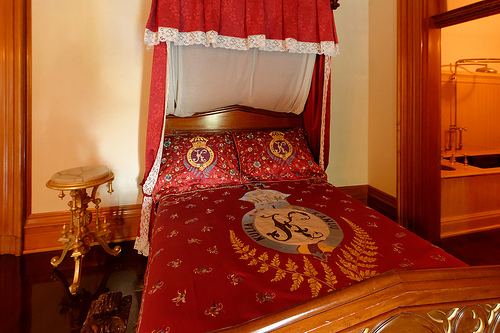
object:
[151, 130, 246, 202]
pillow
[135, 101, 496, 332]
bed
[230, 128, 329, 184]
pillow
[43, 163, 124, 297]
table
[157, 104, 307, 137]
headboard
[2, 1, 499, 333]
bedroom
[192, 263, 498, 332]
footboard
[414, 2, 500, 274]
doorway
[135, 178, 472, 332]
blanket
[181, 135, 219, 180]
design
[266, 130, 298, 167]
design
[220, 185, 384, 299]
design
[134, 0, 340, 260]
curtain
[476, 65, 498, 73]
shower head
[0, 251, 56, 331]
floor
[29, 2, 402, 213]
wall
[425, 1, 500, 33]
beam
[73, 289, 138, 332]
object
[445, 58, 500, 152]
fixture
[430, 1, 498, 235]
bathroom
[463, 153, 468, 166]
fixture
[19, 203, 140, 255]
baseboard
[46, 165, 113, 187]
top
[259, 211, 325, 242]
k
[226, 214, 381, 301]
wreath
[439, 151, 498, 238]
bathtub